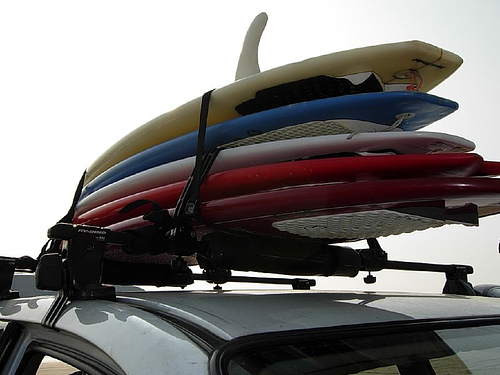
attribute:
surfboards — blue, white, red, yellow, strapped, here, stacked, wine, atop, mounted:
[110, 97, 347, 313]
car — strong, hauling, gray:
[122, 280, 287, 356]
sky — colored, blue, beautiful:
[68, 43, 151, 105]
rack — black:
[177, 230, 435, 344]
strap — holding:
[145, 90, 222, 172]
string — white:
[356, 118, 445, 161]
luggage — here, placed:
[113, 139, 309, 305]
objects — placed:
[30, 161, 191, 301]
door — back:
[30, 327, 69, 368]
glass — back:
[368, 330, 475, 368]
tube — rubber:
[161, 224, 233, 257]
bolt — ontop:
[184, 280, 245, 315]